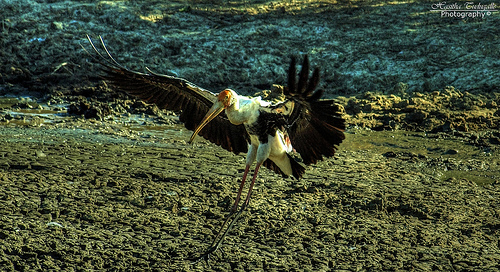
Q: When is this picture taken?
A: At daytime.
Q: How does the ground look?
A: Muddy.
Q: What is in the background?
A: Grass.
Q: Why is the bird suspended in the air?
A: It's landing.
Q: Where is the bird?
A: Above the mud.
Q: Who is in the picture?
A: A stork.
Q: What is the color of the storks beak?
A: Orange.